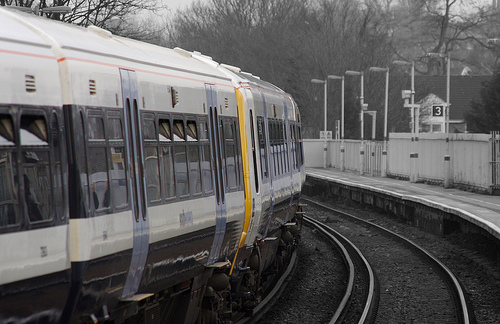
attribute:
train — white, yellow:
[7, 13, 306, 280]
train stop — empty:
[320, 68, 499, 217]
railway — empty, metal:
[308, 195, 499, 323]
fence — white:
[309, 137, 491, 190]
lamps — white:
[311, 51, 465, 130]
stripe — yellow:
[232, 83, 251, 277]